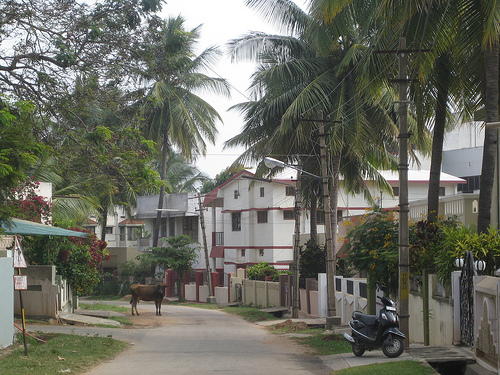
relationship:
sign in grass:
[12, 235, 27, 268] [0, 330, 134, 374]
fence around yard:
[177, 243, 285, 308] [187, 279, 334, 298]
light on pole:
[256, 143, 286, 180] [266, 157, 341, 321]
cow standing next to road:
[129, 283, 167, 316] [86, 286, 327, 373]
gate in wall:
[456, 245, 478, 347] [407, 245, 499, 372]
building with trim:
[163, 168, 467, 306] [216, 204, 288, 212]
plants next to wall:
[338, 209, 498, 297] [320, 272, 497, 360]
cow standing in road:
[129, 283, 167, 316] [71, 295, 331, 373]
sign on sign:
[7, 235, 30, 271] [13, 273, 30, 290]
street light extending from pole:
[260, 152, 320, 186] [313, 111, 338, 321]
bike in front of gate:
[344, 296, 406, 358] [457, 250, 482, 347]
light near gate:
[474, 260, 486, 274] [457, 250, 473, 348]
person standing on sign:
[14, 237, 21, 264] [9, 232, 31, 290]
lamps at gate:
[439, 247, 497, 315] [414, 261, 498, 355]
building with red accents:
[201, 169, 326, 305] [222, 194, 287, 253]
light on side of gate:
[474, 260, 486, 274] [458, 247, 476, 348]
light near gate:
[453, 257, 470, 272] [457, 298, 479, 350]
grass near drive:
[12, 330, 114, 366] [61, 286, 335, 371]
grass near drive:
[296, 332, 353, 355] [322, 346, 473, 368]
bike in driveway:
[344, 296, 406, 358] [318, 328, 474, 367]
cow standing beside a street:
[126, 280, 166, 316] [72, 295, 332, 373]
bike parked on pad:
[344, 296, 406, 358] [332, 340, 461, 364]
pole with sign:
[16, 288, 30, 355] [3, 229, 38, 289]